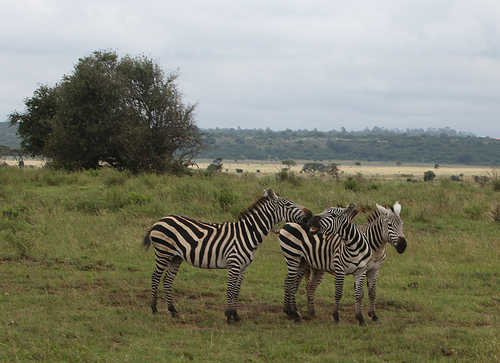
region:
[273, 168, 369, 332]
this is a zebra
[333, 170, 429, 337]
this is a zebra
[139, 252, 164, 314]
the foot of a zebra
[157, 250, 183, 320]
the foot of a zebra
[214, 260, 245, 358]
the foot of a zebra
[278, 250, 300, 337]
the foot of a zebra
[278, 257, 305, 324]
the foot of a zebra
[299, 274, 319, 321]
the foot of a zebra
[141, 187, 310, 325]
black and white zebra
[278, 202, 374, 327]
zebra standing on grass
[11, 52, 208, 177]
tree with green leaves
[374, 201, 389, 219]
white ear on zebra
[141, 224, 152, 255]
black tail on zebra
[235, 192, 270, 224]
brown mane on zebra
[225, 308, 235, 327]
black hoof on zebra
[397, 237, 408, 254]
black nose of zebra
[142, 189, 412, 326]
three zebras on grass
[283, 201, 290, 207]
black eye on zebra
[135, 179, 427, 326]
Zebras standing in a field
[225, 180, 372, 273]
Two zebras play biting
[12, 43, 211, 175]
big bushy tree in field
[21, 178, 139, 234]
Tall green grass in field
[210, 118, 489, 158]
hills in the background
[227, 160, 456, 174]
sand in the background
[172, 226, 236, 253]
black and white stripes on zebra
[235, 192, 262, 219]
brown mane of neck of zebra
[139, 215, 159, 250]
brown tail on butt of zebra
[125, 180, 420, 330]
Group of zebras standing in the grass.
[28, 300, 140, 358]
Green grass covering the ground.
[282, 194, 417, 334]
Two young zebras standing together.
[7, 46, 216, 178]
Large tree growing wildly.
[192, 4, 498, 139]
Overcast sky filled with clouds.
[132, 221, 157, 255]
Short tail of the zebra.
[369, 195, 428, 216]
White pointy ears of the zebra.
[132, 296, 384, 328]
All black hooves of the zebras.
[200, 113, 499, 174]
Hillside covered in bushes and greenery.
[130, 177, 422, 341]
These are zebras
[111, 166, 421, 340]
There are three zebras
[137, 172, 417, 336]
The zebras are striped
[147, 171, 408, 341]
The zebras are black and white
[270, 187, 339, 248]
These zebras are touching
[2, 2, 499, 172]
The sky is dark and cloudy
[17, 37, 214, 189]
There is a tree in the background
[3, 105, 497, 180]
There are trees in the background landscape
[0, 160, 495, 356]
The zebras are in a field of grass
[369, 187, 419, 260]
This zebra is looking to the size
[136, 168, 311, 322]
black and white zebra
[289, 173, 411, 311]
black and white zebra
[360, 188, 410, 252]
black and white zebra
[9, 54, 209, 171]
large green tree in field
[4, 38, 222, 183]
large green tree in field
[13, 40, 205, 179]
large green tree in field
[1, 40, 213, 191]
large green tree in field